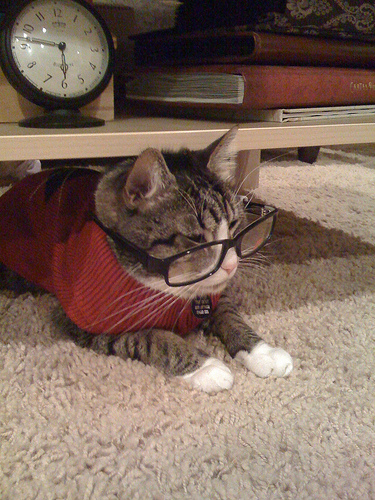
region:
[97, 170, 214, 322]
a cat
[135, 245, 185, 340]
a cat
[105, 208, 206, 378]
a cat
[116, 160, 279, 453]
a cat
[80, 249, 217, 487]
a cat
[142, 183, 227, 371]
a cat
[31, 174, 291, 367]
Cat is lying in carpet.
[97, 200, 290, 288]
Eye glass is black color.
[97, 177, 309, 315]
Cat is wearing eye glass.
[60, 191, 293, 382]
Cat is grey and white color.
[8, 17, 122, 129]
Clock is above the cat.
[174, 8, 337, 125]
Books are arranged in the rack.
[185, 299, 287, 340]
Claws are white color.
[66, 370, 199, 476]
Carpet is grey color.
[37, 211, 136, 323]
Cat is wearing red dress.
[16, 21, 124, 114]
5.47 is the time shown in clock.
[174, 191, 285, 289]
a cat wearing spectacles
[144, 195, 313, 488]
a cat wearing spectacles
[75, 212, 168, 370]
a cat wearing spectacles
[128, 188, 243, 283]
a cat wearing spectacles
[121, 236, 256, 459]
a cat wearing spectacles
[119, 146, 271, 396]
a cat wearing spectacles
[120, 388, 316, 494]
a beige carpet.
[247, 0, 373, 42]
a folded piece of material.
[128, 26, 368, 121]
three books on a table.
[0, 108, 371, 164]
a long wooden table.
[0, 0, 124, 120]
the clock says 5:47.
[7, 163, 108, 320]
a cat is wearing a red black and yellow sweater.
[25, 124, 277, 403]
the cat has black and grey stripes.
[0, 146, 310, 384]
a cat is laying on a rug.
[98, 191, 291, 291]
a cat is wearing glasses.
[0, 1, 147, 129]
the clock is black and white.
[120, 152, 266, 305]
cat wears glasses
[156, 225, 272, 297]
glasses are black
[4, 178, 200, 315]
cat wears red sweater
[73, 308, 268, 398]
cat has white and striped paws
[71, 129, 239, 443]
cat is lying under table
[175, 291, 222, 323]
cat has black and white tag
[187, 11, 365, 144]
books on bottom of table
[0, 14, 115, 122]
clock on table above cat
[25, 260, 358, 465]
carpet is grey and textured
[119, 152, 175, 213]
cat has grey ears